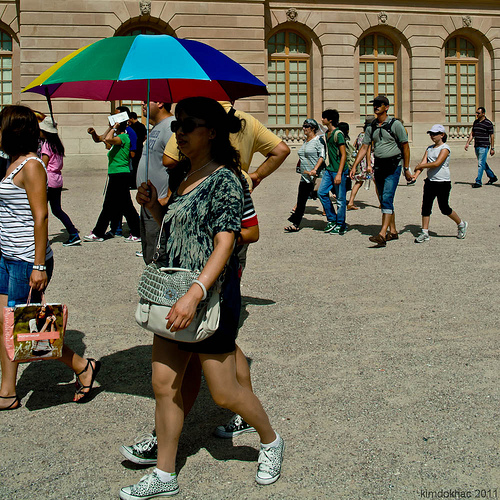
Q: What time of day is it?
A: Daytime.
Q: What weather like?
A: Sunny.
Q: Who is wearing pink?
A: Lady to the left in back.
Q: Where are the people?
A: Outside building.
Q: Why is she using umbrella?
A: Protect from sun.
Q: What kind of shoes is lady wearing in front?
A: Polka dot.